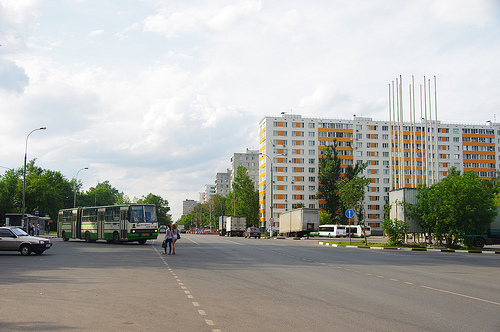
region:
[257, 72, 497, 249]
a tall building on the street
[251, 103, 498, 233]
the building is white and orange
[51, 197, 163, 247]
a bus turning out towards the street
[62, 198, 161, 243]
the bus is white and green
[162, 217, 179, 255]
girls walking towards the bus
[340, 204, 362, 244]
a blue street sign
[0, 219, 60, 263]
a parked silver car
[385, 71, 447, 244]
a building behind the trees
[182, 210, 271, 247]
cars parked along the street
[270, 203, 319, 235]
a trailer parked on the street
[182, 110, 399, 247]
buildings in the background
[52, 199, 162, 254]
a long bus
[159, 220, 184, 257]
two ladies walking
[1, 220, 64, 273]
a brown car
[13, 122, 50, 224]
a street light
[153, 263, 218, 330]
a broken white paint on the road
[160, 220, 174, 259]
a lady carrying a hand bag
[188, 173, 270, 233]
trees on the sidewalk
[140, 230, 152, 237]
a plate number of a bus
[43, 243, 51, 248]
a plate number of the car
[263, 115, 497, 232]
white and oranges buildings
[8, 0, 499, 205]
white cloudy sky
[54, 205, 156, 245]
large beige and green bus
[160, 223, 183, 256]
two people walking in the street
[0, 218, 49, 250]
small gray car parked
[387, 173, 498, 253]
little green bushes in the right side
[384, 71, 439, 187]
large white poles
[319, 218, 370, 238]
two white buses standing next to each other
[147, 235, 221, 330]
white lines in pavement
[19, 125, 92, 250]
two large grey lamppost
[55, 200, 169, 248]
green and cream colored transit bus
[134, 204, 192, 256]
two girl walking towards bus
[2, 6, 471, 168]
fluffy white and gray clouds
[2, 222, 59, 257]
tan colored compact car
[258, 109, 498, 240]
white and orange multi story building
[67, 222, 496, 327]
light gray paved road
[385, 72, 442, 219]
white tall metal pipes sticking up in air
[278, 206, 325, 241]
semi truck trailer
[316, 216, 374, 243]
two buses parked in parking lot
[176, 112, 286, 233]
row of buildings and trees along paved road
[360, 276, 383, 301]
part of a road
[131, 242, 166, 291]
edge of a road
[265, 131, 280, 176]
edge of a building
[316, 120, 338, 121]
top of a building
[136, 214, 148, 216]
window of a bus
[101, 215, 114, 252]
door of a bus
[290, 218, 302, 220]
part of a trailer